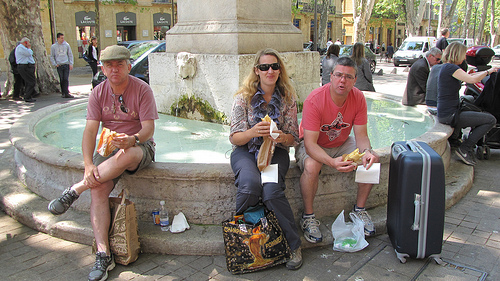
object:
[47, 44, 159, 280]
man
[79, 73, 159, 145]
shirt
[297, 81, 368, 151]
shirt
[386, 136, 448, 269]
suitcase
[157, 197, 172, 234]
bottle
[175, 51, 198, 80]
lion head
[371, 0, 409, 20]
trees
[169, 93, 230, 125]
algae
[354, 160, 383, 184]
napkin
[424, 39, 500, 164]
woman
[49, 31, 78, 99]
man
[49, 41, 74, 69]
shirt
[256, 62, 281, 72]
sunglasses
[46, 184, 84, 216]
shoe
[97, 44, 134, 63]
cap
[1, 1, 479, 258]
fountain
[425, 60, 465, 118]
shirt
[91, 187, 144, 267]
bag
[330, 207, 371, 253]
bag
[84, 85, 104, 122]
sleeve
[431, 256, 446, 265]
wheel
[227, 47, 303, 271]
woman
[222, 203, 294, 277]
bag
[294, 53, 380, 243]
man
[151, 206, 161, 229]
can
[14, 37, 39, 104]
man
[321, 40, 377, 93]
two women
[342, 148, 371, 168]
sandwich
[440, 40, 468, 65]
hair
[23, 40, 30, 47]
phone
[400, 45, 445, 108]
man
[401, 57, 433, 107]
suit